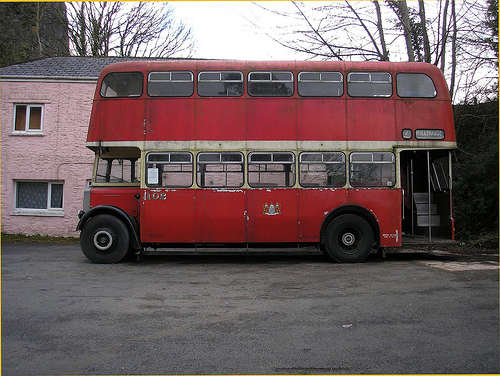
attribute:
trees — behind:
[26, 8, 195, 56]